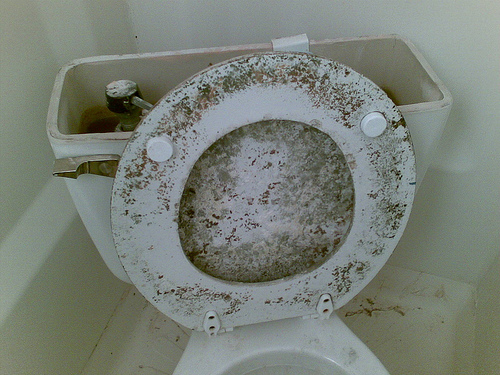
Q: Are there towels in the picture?
A: No, there are no towels.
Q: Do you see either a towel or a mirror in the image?
A: No, there are no towels or mirrors.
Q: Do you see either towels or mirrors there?
A: No, there are no towels or mirrors.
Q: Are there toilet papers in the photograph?
A: No, there are no toilet papers.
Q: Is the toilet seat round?
A: Yes, the toilet seat is round.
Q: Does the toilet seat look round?
A: Yes, the toilet seat is round.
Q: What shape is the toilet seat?
A: The toilet seat is round.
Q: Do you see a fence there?
A: No, there are no fences.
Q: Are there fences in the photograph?
A: No, there are no fences.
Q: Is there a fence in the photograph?
A: No, there are no fences.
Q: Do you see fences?
A: No, there are no fences.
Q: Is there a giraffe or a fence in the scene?
A: No, there are no fences or giraffes.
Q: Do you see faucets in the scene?
A: No, there are no faucets.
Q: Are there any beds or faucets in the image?
A: No, there are no faucets or beds.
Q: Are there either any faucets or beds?
A: No, there are no faucets or beds.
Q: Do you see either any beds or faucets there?
A: No, there are no faucets or beds.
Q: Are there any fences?
A: No, there are no fences.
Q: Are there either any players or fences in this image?
A: No, there are no fences or players.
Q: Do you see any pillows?
A: No, there are no pillows.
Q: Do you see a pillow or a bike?
A: No, there are no pillows or bikes.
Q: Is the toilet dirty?
A: Yes, the toilet is dirty.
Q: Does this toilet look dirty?
A: Yes, the toilet is dirty.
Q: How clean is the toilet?
A: The toilet is dirty.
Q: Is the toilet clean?
A: No, the toilet is dirty.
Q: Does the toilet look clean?
A: No, the toilet is dirty.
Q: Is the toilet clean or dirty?
A: The toilet is dirty.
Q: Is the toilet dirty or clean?
A: The toilet is dirty.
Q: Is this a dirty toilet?
A: Yes, this is a dirty toilet.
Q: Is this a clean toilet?
A: No, this is a dirty toilet.